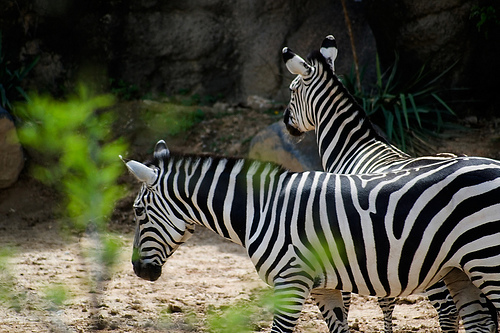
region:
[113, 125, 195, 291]
Head of a zebra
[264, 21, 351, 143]
Head of a zebra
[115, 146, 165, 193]
Ear of a zebra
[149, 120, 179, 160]
Ear of a zebra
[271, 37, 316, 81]
Ear of a zebra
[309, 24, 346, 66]
Ear of a zebra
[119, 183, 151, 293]
Face of a zebra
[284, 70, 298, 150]
Face of a zebra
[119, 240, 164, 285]
Mouth of a zebra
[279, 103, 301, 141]
Mouth of a zebra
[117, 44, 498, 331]
Two stripped zebras in a park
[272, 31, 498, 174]
The zebra with its head high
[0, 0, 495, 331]
Green plants in the background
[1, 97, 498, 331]
The bare soiled space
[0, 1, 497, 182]
A rocky cliff in the background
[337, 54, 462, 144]
The grassy plant on the right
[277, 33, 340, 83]
The sharply alert zebra ears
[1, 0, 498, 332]
A bright day in a park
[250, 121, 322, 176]
The partially blocked central rock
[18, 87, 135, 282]
A faint green plant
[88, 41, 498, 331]
two zebras standing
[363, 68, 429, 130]
fronds beside the zebra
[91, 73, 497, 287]
the zebra are striped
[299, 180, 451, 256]
the stripes are black and white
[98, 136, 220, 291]
the head of the zebra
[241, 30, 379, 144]
the head of the zebra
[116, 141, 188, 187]
the ears of the zebra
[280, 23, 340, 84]
the ears of the zebra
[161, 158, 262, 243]
the neck of the zebra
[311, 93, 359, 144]
the neck of the zebra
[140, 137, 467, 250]
this is a zebra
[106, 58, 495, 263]
the zebras are two in number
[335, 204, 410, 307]
the zebra has white and black strips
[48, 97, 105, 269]
this is a tree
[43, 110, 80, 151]
the leaves are green in color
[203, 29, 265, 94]
this is a rock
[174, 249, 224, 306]
this is the ground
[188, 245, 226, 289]
the ground is bare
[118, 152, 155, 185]
this is the ear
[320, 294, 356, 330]
this is the front leg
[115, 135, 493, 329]
the zebra is black and white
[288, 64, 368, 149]
the strips are black and white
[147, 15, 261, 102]
the rock is grey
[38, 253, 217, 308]
the ground has sand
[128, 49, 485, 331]
the zebras are two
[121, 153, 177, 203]
the ear is black and white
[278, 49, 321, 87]
the ear is black and white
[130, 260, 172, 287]
the nose is black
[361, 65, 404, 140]
the plant is betwween the rocks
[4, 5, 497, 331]
the scene is outdoors